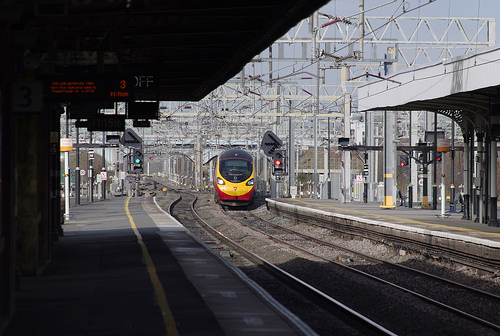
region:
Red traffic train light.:
[271, 155, 288, 168]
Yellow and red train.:
[213, 144, 259, 203]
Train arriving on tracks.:
[213, 149, 260, 221]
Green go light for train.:
[131, 148, 144, 167]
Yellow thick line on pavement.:
[120, 195, 150, 309]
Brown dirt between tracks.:
[245, 234, 266, 246]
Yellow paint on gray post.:
[382, 117, 397, 207]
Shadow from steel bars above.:
[447, 57, 472, 91]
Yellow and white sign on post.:
[61, 137, 72, 217]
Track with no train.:
[167, 173, 202, 220]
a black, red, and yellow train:
[210, 145, 258, 210]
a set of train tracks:
[219, 204, 499, 327]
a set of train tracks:
[155, 177, 399, 334]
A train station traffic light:
[131, 145, 146, 168]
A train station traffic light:
[271, 146, 288, 168]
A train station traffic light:
[396, 153, 407, 168]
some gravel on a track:
[159, 178, 499, 335]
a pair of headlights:
[214, 178, 256, 188]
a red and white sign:
[100, 169, 107, 180]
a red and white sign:
[356, 172, 363, 184]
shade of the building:
[94, 202, 337, 334]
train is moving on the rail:
[209, 131, 309, 270]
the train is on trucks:
[211, 140, 260, 215]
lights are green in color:
[126, 144, 153, 179]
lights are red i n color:
[270, 151, 312, 190]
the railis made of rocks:
[310, 212, 400, 309]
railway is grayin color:
[323, 234, 386, 289]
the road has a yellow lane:
[101, 177, 158, 261]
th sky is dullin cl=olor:
[362, 14, 433, 50]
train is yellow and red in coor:
[226, 151, 261, 216]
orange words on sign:
[48, 78, 105, 94]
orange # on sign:
[116, 77, 128, 91]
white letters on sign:
[131, 72, 156, 88]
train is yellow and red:
[212, 148, 257, 203]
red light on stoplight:
[272, 155, 287, 173]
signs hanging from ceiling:
[45, 67, 160, 106]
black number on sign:
[16, 82, 38, 108]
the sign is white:
[9, 77, 46, 114]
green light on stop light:
[133, 154, 144, 169]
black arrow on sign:
[262, 131, 282, 156]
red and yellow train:
[198, 148, 262, 203]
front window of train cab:
[223, 156, 245, 169]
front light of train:
[215, 178, 228, 186]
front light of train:
[244, 180, 250, 185]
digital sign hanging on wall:
[38, 64, 133, 102]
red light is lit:
[271, 159, 284, 173]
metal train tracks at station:
[164, 171, 491, 333]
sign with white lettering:
[125, 75, 161, 87]